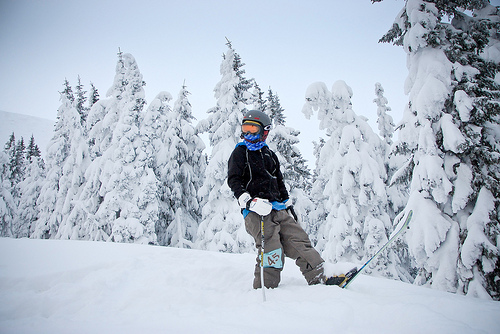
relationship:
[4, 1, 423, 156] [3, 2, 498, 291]
sky behind trees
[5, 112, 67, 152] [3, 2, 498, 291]
mountain behind trees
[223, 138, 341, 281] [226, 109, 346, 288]
jacket on skier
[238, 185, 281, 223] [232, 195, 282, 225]
glove on hand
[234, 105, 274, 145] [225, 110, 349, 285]
helmet on person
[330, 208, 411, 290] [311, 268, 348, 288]
ski on foot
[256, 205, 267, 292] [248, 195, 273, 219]
ski pole in hand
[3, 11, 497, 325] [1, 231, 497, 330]
snow covering ground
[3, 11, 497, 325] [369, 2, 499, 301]
snow covering tree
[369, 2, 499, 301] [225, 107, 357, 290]
tree beside man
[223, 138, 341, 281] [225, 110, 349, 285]
jacket on person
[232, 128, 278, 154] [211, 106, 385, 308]
scarf on person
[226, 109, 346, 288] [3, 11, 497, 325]
skier in snow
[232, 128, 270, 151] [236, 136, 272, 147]
scarf around neck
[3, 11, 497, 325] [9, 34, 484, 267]
snow covers trees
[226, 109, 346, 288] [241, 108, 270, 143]
skier has helmet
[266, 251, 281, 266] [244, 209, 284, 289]
number on leg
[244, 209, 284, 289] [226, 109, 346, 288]
leg of skier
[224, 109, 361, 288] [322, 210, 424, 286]
person wearing skis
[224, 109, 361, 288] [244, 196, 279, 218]
person wearing glove